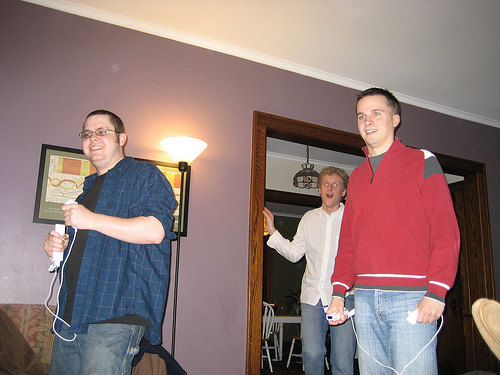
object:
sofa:
[0, 294, 190, 373]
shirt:
[327, 135, 466, 306]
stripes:
[315, 260, 449, 303]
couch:
[0, 298, 190, 372]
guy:
[48, 109, 179, 374]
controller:
[54, 223, 65, 268]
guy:
[326, 87, 460, 373]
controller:
[326, 310, 352, 321]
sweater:
[331, 144, 460, 300]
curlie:
[319, 166, 348, 186]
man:
[263, 165, 355, 373]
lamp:
[160, 135, 209, 364]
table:
[265, 317, 308, 363]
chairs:
[261, 301, 275, 372]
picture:
[32, 141, 193, 238]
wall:
[1, 0, 266, 373]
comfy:
[1, 305, 167, 374]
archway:
[245, 108, 499, 374]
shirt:
[49, 156, 179, 345]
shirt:
[365, 151, 388, 174]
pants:
[300, 295, 357, 374]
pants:
[51, 319, 146, 374]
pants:
[353, 286, 441, 374]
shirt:
[271, 203, 344, 305]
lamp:
[292, 142, 319, 190]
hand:
[326, 295, 348, 326]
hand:
[43, 230, 69, 258]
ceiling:
[270, 137, 367, 179]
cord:
[45, 227, 79, 341]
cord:
[347, 312, 444, 374]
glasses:
[79, 126, 115, 139]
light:
[160, 134, 209, 170]